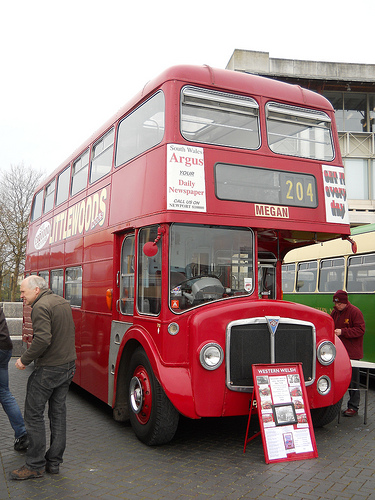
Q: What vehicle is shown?
A: A bus.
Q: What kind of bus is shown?
A: Double decker.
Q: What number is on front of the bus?
A: 204.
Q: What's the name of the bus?
A: Megan.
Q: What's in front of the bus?
A: A sign.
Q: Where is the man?
A: Next to the bus.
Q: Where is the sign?
A: In front of the bus.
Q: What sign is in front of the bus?
A: Red.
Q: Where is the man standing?
A: Near a bus.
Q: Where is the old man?
A: Near a bus.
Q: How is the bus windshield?
A: A large front.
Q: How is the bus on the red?
A: Red in color.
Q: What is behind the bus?
A: Building.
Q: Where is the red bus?
A: Parked on the roadside.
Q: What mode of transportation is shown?
A: Buses.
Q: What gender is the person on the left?
A: Male.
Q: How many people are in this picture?
A: Three.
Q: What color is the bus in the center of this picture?
A: Red.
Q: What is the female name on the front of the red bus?
A: Megan.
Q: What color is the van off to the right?
A: Green and white.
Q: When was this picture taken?
A: Day time.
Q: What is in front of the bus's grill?
A: A red sign.